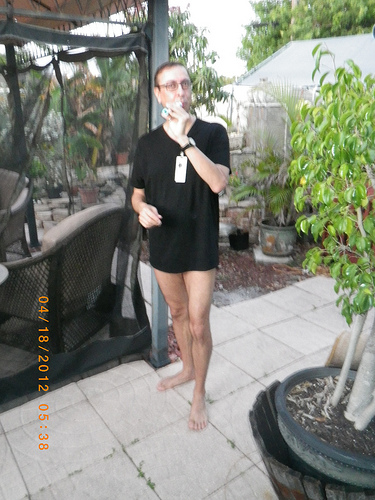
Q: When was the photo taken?
A: Daytime.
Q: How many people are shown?
A: One.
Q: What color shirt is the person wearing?
A: Black.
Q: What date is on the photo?
A: 4/18/2012.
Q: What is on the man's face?
A: Glasses.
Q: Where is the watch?
A: Man's wrist.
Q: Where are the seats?
A: Left side of image.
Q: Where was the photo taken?
A: On a patio.